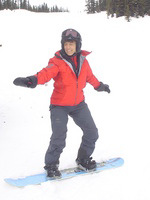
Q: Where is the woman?
A: On a mountain.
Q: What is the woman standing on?
A: It's a snowboard.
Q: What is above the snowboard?
A: A woman.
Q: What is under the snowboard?
A: It's snow.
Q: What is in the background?
A: It's trees.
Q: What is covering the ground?
A: It's snow.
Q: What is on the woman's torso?
A: A jacket.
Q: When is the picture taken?
A: Daytime.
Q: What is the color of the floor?
A: White.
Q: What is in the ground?
A: Snow.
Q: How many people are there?
A: 1.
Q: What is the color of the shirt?
A: Red.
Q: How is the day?
A: Sunny.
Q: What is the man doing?
A: Skating.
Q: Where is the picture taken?
A: In the mountains.